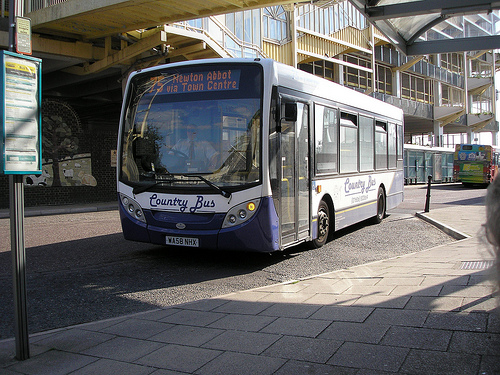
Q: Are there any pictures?
A: No, there are no pictures.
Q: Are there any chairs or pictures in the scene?
A: No, there are no pictures or chairs.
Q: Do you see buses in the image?
A: Yes, there is a bus.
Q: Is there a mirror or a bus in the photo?
A: Yes, there is a bus.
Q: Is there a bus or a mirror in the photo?
A: Yes, there is a bus.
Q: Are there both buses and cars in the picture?
A: No, there is a bus but no cars.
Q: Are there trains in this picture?
A: No, there are no trains.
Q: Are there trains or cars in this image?
A: No, there are no trains or cars.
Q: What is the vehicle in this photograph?
A: The vehicle is a bus.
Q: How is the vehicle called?
A: The vehicle is a bus.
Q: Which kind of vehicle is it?
A: The vehicle is a bus.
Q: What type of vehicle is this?
A: This is a bus.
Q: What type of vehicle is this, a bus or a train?
A: This is a bus.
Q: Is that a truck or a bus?
A: That is a bus.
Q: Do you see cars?
A: No, there are no cars.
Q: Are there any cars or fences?
A: No, there are no cars or fences.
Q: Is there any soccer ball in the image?
A: No, there are no soccer balls.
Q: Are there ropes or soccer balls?
A: No, there are no soccer balls or ropes.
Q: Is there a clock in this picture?
A: No, there are no clocks.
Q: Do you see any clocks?
A: No, there are no clocks.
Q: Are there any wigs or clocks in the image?
A: No, there are no clocks or wigs.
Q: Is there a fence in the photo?
A: No, there are no fences.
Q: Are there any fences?
A: No, there are no fences.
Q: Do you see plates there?
A: Yes, there is a plate.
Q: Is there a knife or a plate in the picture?
A: Yes, there is a plate.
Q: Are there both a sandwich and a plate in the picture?
A: No, there is a plate but no sandwiches.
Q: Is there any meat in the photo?
A: No, there is no meat.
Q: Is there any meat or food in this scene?
A: No, there are no meat or food.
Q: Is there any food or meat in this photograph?
A: No, there are no meat or food.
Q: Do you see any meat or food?
A: No, there are no meat or food.